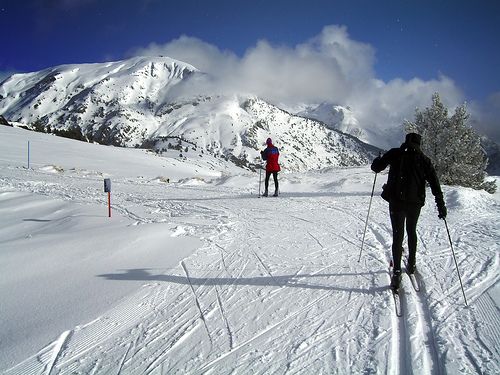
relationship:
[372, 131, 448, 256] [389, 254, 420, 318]
person on snow skis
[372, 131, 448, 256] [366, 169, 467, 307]
person holding ski poles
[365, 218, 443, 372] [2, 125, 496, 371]
tracks in snow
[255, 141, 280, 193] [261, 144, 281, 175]
person wearing a coat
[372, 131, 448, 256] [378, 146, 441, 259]
person wearing black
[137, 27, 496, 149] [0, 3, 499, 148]
clouds in sky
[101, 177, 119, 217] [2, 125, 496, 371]
post in snow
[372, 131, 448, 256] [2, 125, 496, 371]
person standing in snow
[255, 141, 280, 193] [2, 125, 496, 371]
person standing in snow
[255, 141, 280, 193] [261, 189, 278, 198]
person on skis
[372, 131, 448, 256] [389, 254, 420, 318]
person wearing snow skis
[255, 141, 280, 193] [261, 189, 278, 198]
person wearing skis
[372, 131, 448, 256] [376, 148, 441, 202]
person wearing a jacket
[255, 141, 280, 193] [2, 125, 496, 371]
person walking in snow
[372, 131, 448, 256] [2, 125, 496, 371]
person skiing in snow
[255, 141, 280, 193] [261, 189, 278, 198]
person walking with skis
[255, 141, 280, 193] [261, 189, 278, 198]
person standing with skis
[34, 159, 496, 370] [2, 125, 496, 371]
track marks in snow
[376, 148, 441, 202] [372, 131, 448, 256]
jacket of person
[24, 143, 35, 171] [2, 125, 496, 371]
pole in snow